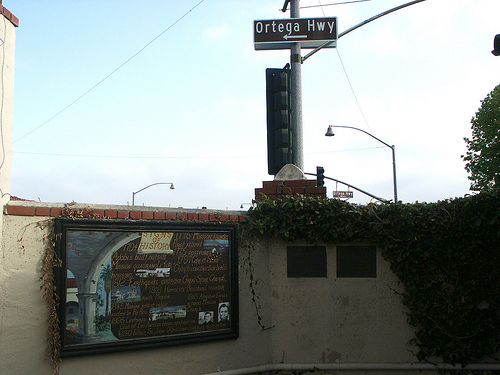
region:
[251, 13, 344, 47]
Directional sign attached to utility pole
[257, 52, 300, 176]
Traffic light attached to utility pole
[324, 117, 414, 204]
Streetlight for street in the background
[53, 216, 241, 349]
Large sign attached to the wall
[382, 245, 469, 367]
Ivy growing on the wall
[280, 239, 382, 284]
Plaques attached to the wall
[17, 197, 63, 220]
Line of bricks across the top of all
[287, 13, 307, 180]
Utility poles supporting traffic devices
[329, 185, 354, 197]
Street sign attached to utility pole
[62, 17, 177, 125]
Electrical wire strung between utility poles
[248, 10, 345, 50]
Sign that reads Ortega Hwy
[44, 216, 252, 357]
Old picture in a frame.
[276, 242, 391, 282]
Two squares on the wall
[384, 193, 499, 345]
Ivy growing over the wall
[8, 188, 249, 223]
Brick accent on the wall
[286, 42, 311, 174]
Steel sign post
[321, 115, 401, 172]
Street light over hanging the road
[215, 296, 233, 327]
Picture of Abraham Lincoln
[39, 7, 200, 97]
Electric wires running across the street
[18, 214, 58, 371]
Ivy plant that has died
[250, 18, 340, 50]
a black and white street sign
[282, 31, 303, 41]
a white arrow on the sign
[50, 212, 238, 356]
a large painting on a wall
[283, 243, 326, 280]
a black square in a wall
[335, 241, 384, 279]
a black square in a wall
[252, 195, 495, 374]
green ivy climbing on a wall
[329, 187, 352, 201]
a black and white street sign in the distance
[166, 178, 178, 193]
a hanging light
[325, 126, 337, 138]
a hanging light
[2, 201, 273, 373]
a cream wall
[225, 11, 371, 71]
The sign is on top of the building.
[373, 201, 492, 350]
Green vines growing on the building.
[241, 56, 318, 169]
The traffic signal is black.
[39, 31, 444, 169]
The sky is clear and blue.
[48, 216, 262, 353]
A picture on the side of the building.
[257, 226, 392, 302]
Two small windows on the building.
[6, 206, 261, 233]
The edge of the building is bricks.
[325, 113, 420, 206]
A street light on the pole.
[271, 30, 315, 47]
The sign has a white error.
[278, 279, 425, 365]
The building is beige.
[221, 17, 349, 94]
road sign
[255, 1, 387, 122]
road sign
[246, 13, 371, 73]
road sign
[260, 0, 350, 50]
road sign